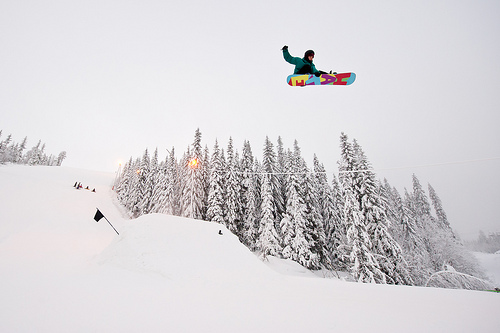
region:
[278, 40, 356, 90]
Snowboarder performing aerial stunt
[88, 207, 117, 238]
Flag marker on ski slope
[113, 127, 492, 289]
Snow covered trees on slope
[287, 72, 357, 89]
Snowboard in aerial stunt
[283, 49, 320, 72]
Winter coat on snowboarder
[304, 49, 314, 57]
Helmet on snowboarder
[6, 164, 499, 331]
Snow covered ski slope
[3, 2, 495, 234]
Cloudy winter sky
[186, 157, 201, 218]
light pole on ski slope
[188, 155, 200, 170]
Illuminated light for ski slope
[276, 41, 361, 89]
snowboarder flying through the air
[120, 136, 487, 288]
snow covered trees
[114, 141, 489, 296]
trees lining the mountainside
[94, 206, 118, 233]
black flag on black pole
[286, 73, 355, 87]
bottom of the snowboard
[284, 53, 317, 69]
blue jacket snowboarder is wearing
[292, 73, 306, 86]
yellow letter on bottom of snowboard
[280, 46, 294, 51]
black glove snowboarder is wearing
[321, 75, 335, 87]
purple letter on bottom of snowboard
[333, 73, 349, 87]
red letter on bottom of snowboard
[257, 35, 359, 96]
man doing tricks in air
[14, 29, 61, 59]
white clouds in blue sky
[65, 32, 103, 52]
white clouds in blue sky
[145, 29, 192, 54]
white clouds in blue sky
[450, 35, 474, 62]
white clouds in blue sky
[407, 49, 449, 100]
white clouds in blue sky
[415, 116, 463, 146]
white clouds in blue sky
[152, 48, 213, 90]
white clouds in blue sky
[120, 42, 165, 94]
white clouds in blue sky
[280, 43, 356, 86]
a person on a snowboard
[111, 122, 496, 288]
trees covered with snow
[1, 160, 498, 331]
snow covered ground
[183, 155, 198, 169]
sun shining through the trees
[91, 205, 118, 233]
a black flag on a pole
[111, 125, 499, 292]
pine trees on a hill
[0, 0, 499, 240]
a gray colored sky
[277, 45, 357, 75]
a green colored coat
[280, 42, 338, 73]
a person wearing a hat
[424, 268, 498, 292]
a pine tree bent over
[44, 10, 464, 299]
a snowboarder flying over the slopes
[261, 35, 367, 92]
this snowboarder is high in the air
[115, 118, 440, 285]
pine trees covered with snow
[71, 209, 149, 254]
a flag in the snow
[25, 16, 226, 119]
a cloudy sky above the area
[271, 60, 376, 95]
the snowboard is colorful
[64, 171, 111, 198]
some people in the background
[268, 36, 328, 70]
this man's arm is extended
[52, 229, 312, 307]
the snow is white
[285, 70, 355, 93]
the word hate is on the bottom of the skateboard